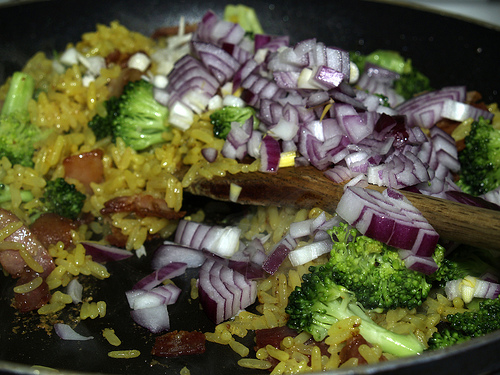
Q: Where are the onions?
A: Top.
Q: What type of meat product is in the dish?
A: Bacon.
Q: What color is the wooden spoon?
A: Brown.